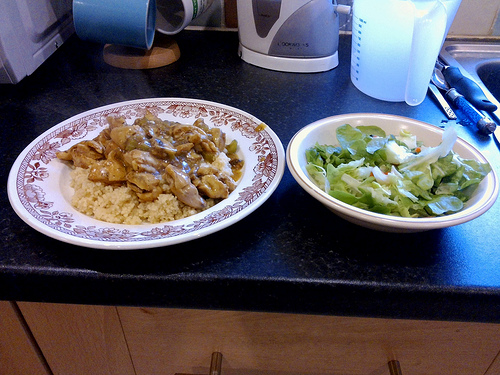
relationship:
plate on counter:
[4, 100, 283, 253] [1, 26, 500, 325]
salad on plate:
[310, 125, 481, 216] [4, 100, 283, 253]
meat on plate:
[67, 120, 231, 206] [4, 100, 283, 253]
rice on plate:
[63, 166, 203, 225] [4, 100, 283, 253]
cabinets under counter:
[35, 304, 427, 374] [0, 39, 500, 322]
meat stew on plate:
[55, 114, 238, 210] [4, 100, 283, 253]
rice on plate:
[68, 151, 235, 224] [4, 100, 283, 253]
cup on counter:
[342, 0, 467, 112] [0, 39, 500, 322]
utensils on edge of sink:
[429, 57, 495, 139] [442, 44, 498, 149]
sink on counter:
[442, 44, 498, 149] [0, 39, 500, 322]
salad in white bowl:
[304, 123, 489, 219] [285, 112, 499, 237]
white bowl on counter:
[285, 112, 499, 237] [0, 39, 500, 322]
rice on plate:
[63, 166, 203, 225] [8, 95, 285, 249]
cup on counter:
[345, 0, 464, 108] [0, 39, 500, 322]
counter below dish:
[9, 84, 499, 286] [10, 87, 285, 252]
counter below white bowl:
[9, 84, 499, 286] [285, 112, 499, 237]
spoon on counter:
[430, 67, 496, 134] [0, 39, 500, 322]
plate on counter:
[92, 222, 212, 258] [233, 242, 471, 332]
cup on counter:
[70, 0, 166, 50] [0, 39, 500, 322]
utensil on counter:
[433, 67, 495, 137] [0, 39, 500, 322]